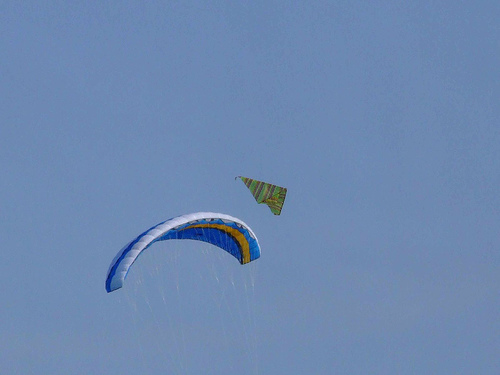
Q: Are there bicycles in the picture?
A: No, there are no bicycles.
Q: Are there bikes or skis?
A: No, there are no bikes or skis.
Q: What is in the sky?
A: The clouds are in the sky.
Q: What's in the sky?
A: The clouds are in the sky.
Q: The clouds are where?
A: The clouds are in the sky.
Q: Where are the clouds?
A: The clouds are in the sky.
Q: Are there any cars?
A: No, there are no cars.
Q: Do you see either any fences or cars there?
A: No, there are no cars or fences.